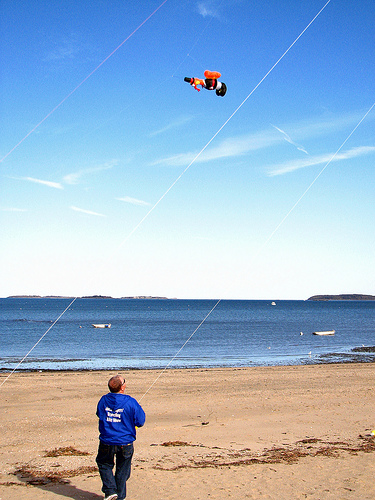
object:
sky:
[2, 1, 370, 297]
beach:
[2, 366, 373, 498]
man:
[91, 376, 148, 496]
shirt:
[94, 391, 147, 444]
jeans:
[90, 437, 134, 499]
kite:
[181, 68, 230, 98]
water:
[0, 293, 371, 369]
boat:
[312, 326, 337, 338]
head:
[106, 374, 129, 396]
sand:
[192, 401, 325, 476]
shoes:
[97, 489, 118, 499]